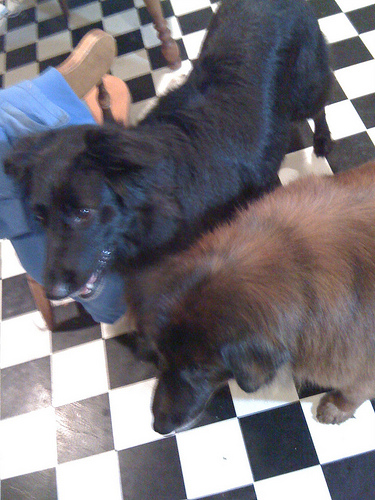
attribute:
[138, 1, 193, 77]
leg — wood, brown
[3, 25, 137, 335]
chair — brown, wood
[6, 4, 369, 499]
floor — black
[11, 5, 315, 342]
dog — black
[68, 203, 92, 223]
eye — round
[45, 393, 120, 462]
tile — white, black